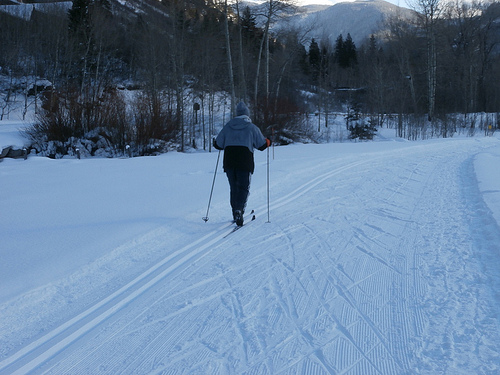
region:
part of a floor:
[278, 299, 301, 334]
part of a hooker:
[234, 174, 303, 256]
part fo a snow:
[306, 279, 338, 311]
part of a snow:
[208, 316, 238, 345]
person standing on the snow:
[190, 109, 290, 243]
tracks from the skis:
[4, 213, 239, 374]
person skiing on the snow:
[203, 98, 282, 234]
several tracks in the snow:
[154, 166, 420, 374]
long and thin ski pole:
[262, 147, 277, 229]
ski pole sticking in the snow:
[262, 144, 275, 230]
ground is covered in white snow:
[2, 108, 499, 370]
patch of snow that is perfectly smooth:
[4, 158, 208, 226]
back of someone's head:
[228, 98, 250, 121]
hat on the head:
[234, 100, 250, 121]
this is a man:
[213, 100, 273, 235]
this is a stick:
[259, 145, 280, 215]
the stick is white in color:
[261, 164, 272, 181]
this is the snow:
[318, 175, 398, 284]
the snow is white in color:
[333, 207, 423, 308]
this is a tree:
[129, 20, 183, 145]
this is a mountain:
[327, 2, 382, 37]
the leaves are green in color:
[338, 35, 355, 59]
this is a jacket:
[224, 123, 258, 170]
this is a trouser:
[231, 174, 252, 199]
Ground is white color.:
[22, 172, 469, 354]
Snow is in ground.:
[19, 160, 484, 350]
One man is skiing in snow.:
[191, 95, 298, 236]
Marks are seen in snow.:
[55, 153, 431, 358]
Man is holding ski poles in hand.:
[195, 100, 276, 232]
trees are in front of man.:
[30, 16, 495, 131]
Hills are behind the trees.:
[255, 1, 405, 51]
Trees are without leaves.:
[76, 12, 441, 122]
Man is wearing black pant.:
[213, 155, 263, 232]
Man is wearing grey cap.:
[226, 90, 268, 147]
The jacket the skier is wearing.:
[215, 120, 262, 174]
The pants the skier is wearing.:
[229, 172, 249, 218]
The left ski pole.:
[208, 148, 218, 222]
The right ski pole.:
[263, 147, 271, 225]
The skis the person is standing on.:
[220, 206, 259, 231]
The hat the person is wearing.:
[231, 102, 246, 115]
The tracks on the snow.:
[21, 169, 486, 373]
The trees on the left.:
[5, 3, 212, 153]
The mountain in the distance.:
[223, 3, 433, 39]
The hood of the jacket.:
[225, 118, 250, 129]